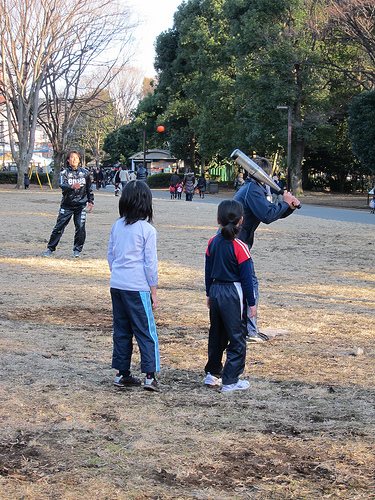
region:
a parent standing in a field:
[42, 142, 98, 267]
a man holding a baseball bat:
[219, 140, 304, 347]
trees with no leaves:
[0, 1, 140, 187]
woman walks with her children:
[165, 161, 203, 202]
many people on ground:
[33, 110, 324, 292]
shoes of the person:
[192, 349, 262, 403]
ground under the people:
[149, 387, 228, 445]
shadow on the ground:
[294, 359, 364, 409]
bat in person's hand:
[229, 139, 300, 207]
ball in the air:
[142, 113, 177, 148]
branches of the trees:
[13, 56, 123, 130]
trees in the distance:
[150, 8, 321, 109]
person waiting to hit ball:
[215, 125, 307, 209]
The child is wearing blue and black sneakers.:
[112, 370, 163, 389]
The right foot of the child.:
[141, 375, 168, 393]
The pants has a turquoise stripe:
[99, 289, 163, 379]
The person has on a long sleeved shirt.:
[95, 220, 168, 286]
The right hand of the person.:
[142, 225, 162, 307]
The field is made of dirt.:
[2, 179, 370, 465]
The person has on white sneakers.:
[200, 373, 254, 398]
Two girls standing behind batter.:
[107, 178, 260, 392]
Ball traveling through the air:
[157, 122, 167, 137]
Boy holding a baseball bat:
[218, 146, 302, 344]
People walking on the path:
[169, 164, 209, 202]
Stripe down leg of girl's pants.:
[138, 288, 162, 369]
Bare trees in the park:
[0, 0, 137, 190]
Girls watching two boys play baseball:
[28, 121, 303, 394]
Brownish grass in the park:
[1, 191, 373, 496]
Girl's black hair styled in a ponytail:
[214, 200, 245, 242]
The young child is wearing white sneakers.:
[203, 368, 253, 394]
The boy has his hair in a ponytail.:
[217, 197, 242, 236]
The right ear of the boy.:
[240, 215, 246, 224]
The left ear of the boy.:
[213, 212, 223, 225]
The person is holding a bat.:
[210, 145, 298, 345]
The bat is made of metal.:
[224, 143, 305, 211]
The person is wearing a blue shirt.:
[221, 178, 282, 250]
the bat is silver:
[223, 139, 280, 200]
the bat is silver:
[220, 135, 295, 221]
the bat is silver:
[225, 135, 280, 209]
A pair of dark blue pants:
[202, 283, 255, 379]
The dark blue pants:
[200, 286, 256, 377]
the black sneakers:
[108, 370, 159, 396]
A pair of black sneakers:
[109, 372, 168, 396]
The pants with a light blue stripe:
[96, 284, 181, 377]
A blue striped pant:
[101, 281, 167, 374]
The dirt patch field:
[4, 255, 368, 498]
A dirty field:
[1, 255, 373, 498]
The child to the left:
[95, 170, 179, 390]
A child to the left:
[98, 173, 175, 392]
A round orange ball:
[150, 114, 171, 138]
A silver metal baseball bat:
[222, 140, 303, 215]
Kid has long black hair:
[107, 169, 158, 229]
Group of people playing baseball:
[32, 113, 310, 400]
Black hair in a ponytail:
[206, 188, 246, 241]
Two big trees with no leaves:
[0, 0, 143, 195]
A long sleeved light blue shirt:
[101, 211, 163, 295]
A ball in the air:
[141, 112, 173, 138]